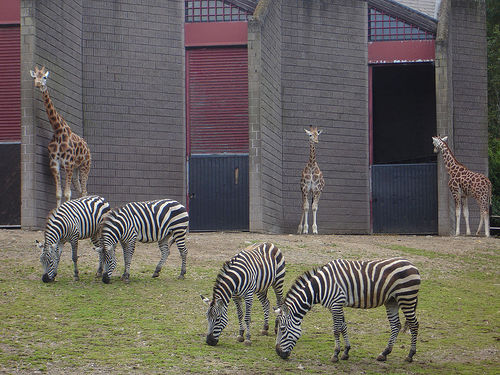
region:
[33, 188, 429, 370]
four zebra grazing on grass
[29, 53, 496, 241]
three giraffes standing along the wall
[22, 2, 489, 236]
gray brick wall behind giraffes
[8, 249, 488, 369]
grass zebras are standing on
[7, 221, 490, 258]
dirt patch giraffes are standing on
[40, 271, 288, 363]
black noses of the zebras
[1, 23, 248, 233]
red and navy blue doors on gray structure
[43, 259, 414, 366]
hooves of the zebras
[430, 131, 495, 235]
giraffe looking into the building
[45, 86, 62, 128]
long neck of tallest giraffe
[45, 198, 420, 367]
the zebras are grazing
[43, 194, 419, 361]
the zebras are white and black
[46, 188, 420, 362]
the zebras have stripes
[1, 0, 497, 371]
scene takes place outdoors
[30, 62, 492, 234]
the giraffes are standing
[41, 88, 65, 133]
the giraffe has a long neck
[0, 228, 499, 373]
the grass is short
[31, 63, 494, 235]
the giraffes have spots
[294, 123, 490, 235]
the two small giraffes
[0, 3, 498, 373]
the animals are outside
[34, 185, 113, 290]
The zebra is black and white.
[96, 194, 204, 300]
The zebra is black and white.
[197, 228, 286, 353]
The zebra is black and white.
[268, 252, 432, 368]
The zebra is black and white.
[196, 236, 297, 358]
The zebra is grazing.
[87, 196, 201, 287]
The zebra is grazing.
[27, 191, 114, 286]
The zebra is grazing.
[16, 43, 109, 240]
The giraffe is standing by the building.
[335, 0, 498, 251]
The giraffe is standing by the building.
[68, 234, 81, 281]
the leg of a black and white zebra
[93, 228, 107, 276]
the leg of a black and white zebra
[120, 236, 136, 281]
the leg of a black and white zebra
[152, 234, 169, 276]
the leg of a black and white zebra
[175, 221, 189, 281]
the leg of a black and white zebra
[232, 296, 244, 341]
the leg of a black and white zebra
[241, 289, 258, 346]
the leg of a black and white zebra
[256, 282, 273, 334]
the leg of a black and white zebra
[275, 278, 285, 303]
the leg of a black and white zebra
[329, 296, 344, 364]
the leg of a black and white zebra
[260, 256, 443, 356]
this is a zebra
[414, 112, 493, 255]
this is a giraffe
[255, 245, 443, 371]
giraffes eating on grass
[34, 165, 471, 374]
zebras facing the same direction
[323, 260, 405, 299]
black stripes on zebra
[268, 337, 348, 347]
black nose on zebra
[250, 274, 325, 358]
zebra with head down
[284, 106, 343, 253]
this is a young giraffe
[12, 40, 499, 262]
there are three giraffes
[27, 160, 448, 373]
there are four zebras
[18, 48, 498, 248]
the giraffes are close to the wall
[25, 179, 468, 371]
the zebras have stripes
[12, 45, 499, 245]
the giraffes are standing against the wall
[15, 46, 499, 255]
the three giraffes are standing against the wall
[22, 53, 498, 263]
the giraffes have spots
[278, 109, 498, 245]
these are young giraffes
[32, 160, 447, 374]
the zebras have black and white stripes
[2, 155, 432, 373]
the zebras are grazing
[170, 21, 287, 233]
the door is black and red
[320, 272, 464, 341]
a zebra in the field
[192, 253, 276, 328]
a zebra in the field